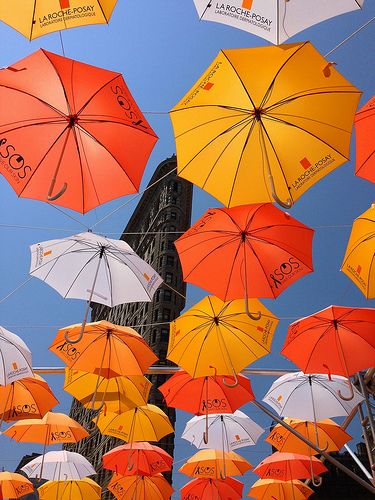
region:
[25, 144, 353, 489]
numerous yellow, white and orange umbrellas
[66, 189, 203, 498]
very tall sknny building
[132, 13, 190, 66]
bright blue sky with no clouds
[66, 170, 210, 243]
wires holding umbrellas together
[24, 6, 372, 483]
picture taken from under umbrellas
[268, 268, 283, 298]
black awareness ribbon on the umbrella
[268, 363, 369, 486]
metal framing to hold wires for umbrellas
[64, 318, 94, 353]
silver handle of umbrella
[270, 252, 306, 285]
letters SOS written in black on umbrella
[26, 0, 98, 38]
company name on umbrella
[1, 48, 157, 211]
orange umbrella in the air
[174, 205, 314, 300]
orange umbrella in the air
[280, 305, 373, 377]
orange umbrella in the air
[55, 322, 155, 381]
light orange umbrella in the air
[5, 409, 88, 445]
light orange umbrella in the air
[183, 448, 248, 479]
light orange umbrella in the air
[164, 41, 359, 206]
yellow umbrella in the air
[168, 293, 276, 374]
yellow umbrella in the air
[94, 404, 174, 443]
yellow umbrella in the air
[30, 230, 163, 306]
a white umbrella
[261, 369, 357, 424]
White umbrella on the wire.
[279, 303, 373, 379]
Orange umbrella on the wires.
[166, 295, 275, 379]
Yellow umbrella on the wires.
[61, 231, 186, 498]
Gray building in the background.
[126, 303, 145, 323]
Windows in the side of the building.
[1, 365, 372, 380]
Metal pole in the background.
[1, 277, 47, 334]
Gray cables holding umbrellas.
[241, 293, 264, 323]
Gray umbrella handle hanging from umbrella.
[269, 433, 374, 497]
Smaller in the background.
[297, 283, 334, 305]
Blue sky in the background.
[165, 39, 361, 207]
Large yellow umbrella next to orange umbrella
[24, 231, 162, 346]
Large white umbrella next to orange umbrella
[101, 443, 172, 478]
Large red umbrella next to orange umbrella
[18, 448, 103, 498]
Large white umbrella next to red umbrella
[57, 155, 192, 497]
Flatiron building behind orange umbrella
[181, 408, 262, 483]
Large white umbrella next to orange umbrella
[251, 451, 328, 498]
Large red umbrella next to orange umbrella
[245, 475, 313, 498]
Large orange umbrella behind red umbrella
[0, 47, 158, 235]
Large red umbrella in front of white umbrella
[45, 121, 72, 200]
Long white handle on red umbrella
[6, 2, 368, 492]
umbrellas suspended in the air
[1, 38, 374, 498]
eight red umbrellas in the air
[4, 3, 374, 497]
seven yellow umbrellas in the air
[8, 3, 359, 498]
six white umbrellas in the air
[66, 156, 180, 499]
building behind umbrealls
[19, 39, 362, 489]
wires suspending umbrellas in air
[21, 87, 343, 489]
handles of umbrellas in the air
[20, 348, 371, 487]
metal bars among umbrellas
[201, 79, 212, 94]
red logo on yellow umbrellas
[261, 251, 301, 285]
black lettering on red umbrellas